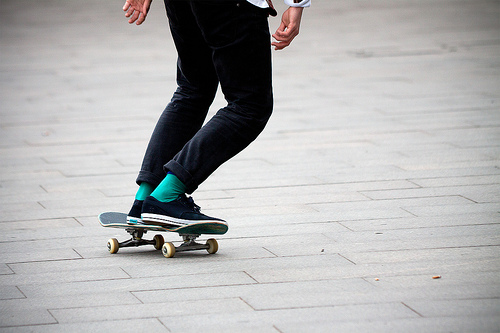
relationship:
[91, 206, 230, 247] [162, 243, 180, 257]
skateboard has wheel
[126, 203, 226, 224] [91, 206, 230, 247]
foot on skateboard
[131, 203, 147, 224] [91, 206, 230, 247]
foot on skateboard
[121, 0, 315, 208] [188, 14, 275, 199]
person has leg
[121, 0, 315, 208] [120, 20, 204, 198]
person has leg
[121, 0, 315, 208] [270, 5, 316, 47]
person has hand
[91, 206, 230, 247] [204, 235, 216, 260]
skateboard has wheel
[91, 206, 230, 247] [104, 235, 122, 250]
skateboard has wheel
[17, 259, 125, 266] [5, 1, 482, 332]
brick on walkway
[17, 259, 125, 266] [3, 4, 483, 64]
brick on walkway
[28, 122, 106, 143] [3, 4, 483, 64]
tile on walkway